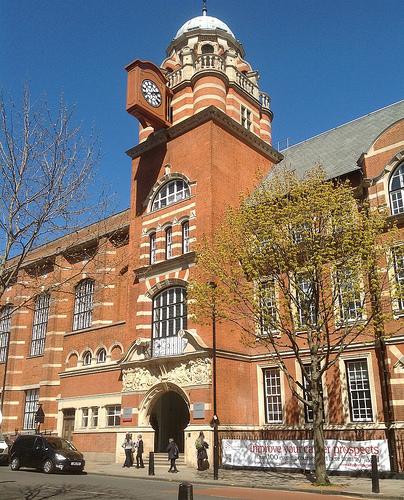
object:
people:
[165, 437, 181, 473]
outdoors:
[0, 0, 404, 500]